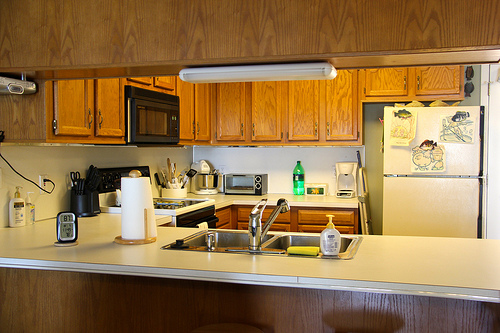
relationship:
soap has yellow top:
[319, 214, 341, 257] [326, 213, 336, 229]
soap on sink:
[319, 214, 341, 257] [160, 228, 366, 260]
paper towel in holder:
[120, 176, 158, 240] [112, 168, 156, 246]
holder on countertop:
[112, 168, 156, 246] [0, 212, 499, 305]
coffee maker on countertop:
[335, 161, 360, 200] [187, 191, 361, 209]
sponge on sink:
[287, 246, 319, 257] [160, 228, 366, 260]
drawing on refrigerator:
[390, 107, 420, 147] [384, 102, 484, 235]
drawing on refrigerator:
[411, 135, 448, 173] [384, 102, 484, 235]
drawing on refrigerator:
[438, 109, 477, 144] [384, 102, 484, 235]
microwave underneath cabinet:
[124, 84, 181, 144] [127, 75, 178, 95]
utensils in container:
[155, 157, 199, 189] [161, 185, 187, 198]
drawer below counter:
[237, 204, 291, 223] [187, 191, 361, 209]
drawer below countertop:
[297, 209, 355, 226] [0, 212, 499, 305]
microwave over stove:
[124, 84, 181, 144] [90, 165, 220, 228]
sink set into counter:
[180, 210, 349, 261] [402, 241, 481, 273]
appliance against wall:
[216, 173, 269, 193] [191, 144, 361, 191]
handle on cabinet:
[323, 118, 333, 136] [287, 85, 359, 142]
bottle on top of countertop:
[292, 160, 305, 195] [2, 195, 498, 305]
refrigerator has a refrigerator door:
[384, 102, 484, 235] [378, 101, 482, 174]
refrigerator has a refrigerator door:
[384, 102, 484, 235] [380, 176, 482, 248]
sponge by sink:
[287, 246, 319, 257] [168, 222, 374, 276]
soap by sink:
[318, 210, 343, 257] [168, 222, 374, 276]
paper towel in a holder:
[120, 176, 158, 240] [112, 168, 156, 244]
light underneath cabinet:
[178, 59, 339, 84] [0, 0, 496, 83]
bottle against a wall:
[289, 160, 306, 196] [192, 147, 364, 194]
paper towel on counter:
[107, 167, 175, 257] [0, 222, 498, 330]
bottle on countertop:
[292, 160, 305, 195] [2, 195, 498, 305]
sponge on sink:
[280, 236, 317, 264] [162, 194, 364, 261]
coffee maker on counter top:
[332, 159, 359, 204] [2, 170, 498, 307]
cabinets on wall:
[220, 92, 352, 150] [32, 23, 493, 247]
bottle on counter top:
[9, 185, 28, 226] [9, 188, 498, 311]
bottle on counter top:
[24, 189, 41, 223] [9, 188, 498, 311]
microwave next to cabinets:
[124, 85, 182, 144] [2, 77, 210, 143]